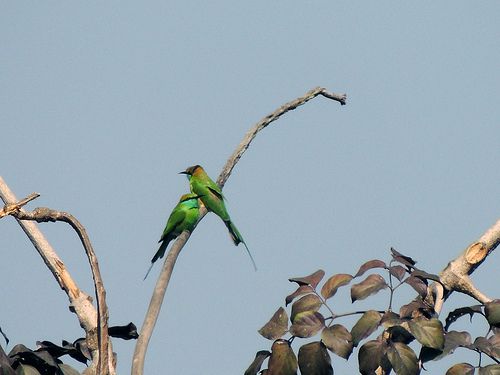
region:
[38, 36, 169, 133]
clear blue sky in photo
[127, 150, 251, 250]
birds in the photo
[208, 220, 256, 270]
tail feather of bird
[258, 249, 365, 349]
leaves next to birds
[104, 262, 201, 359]
branch under the birds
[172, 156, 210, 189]
head of a bird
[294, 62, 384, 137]
top of the branch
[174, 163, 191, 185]
beak of the bird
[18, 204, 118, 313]
branches next to birds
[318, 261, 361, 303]
one leaf in photo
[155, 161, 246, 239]
green birds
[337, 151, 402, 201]
white clouds in blue sky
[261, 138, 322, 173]
white clouds in blue sky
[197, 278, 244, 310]
white clouds in blue sky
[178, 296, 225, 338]
white clouds in blue sky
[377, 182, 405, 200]
white clouds in blue sky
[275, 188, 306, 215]
white clouds in blue sky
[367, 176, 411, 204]
white clouds in blue sky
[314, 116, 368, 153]
white clouds in blue sky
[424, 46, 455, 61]
white clouds in blue sky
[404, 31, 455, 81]
white clouds in blue sky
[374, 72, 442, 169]
white clouds in blue sky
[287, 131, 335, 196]
white clouds in blue sky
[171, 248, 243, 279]
white clouds in blue sky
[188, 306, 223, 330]
white clouds in blue sky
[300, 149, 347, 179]
white clouds in blue sky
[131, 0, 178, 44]
white clouds in blue sky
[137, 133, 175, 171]
white clouds in blue sky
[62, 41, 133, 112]
white clouds in blue sky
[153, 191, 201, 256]
The bird that is on the left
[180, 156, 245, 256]
The bird that is on the right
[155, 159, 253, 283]
Two birds who are sitting next to eachother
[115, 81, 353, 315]
The branch the two birds are sitting on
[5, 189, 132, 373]
The branches on the left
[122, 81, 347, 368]
The branch in the middle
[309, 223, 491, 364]
The branch on the right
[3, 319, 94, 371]
The leaves on the left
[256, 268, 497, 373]
The leaves on the right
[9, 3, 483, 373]
The blue sky behind the birds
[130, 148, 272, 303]
green birds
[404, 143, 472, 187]
white clouds in blue sky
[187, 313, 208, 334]
white clouds in blue sky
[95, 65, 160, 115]
white clouds in blue sky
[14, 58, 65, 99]
white clouds in blue sky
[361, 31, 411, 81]
white clouds in blue sky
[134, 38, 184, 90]
white clouds in blue sky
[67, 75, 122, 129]
white clouds in blue sky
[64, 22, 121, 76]
white clouds in blue sky